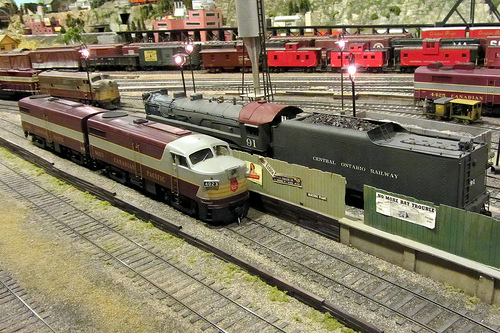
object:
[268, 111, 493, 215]
train car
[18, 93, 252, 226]
train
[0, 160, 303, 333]
tracks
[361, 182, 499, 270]
fence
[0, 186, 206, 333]
grass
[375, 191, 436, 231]
signs